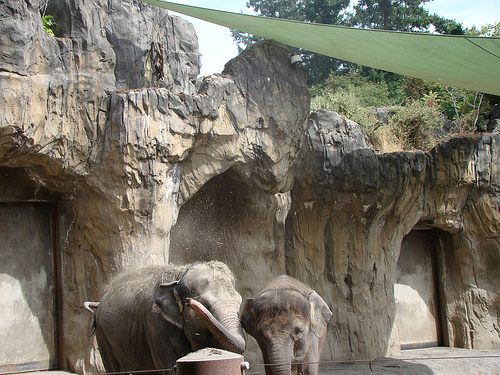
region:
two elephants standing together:
[71, 206, 353, 373]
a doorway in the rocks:
[364, 149, 485, 364]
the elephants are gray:
[70, 249, 345, 371]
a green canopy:
[129, 0, 498, 118]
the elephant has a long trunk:
[69, 251, 274, 373]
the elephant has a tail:
[72, 277, 117, 343]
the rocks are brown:
[19, 14, 484, 271]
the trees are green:
[230, 4, 493, 81]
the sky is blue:
[164, 0, 499, 67]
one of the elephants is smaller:
[78, 246, 346, 373]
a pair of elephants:
[83, 258, 331, 373]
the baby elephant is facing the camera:
[240, 274, 332, 374]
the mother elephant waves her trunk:
[83, 259, 245, 374]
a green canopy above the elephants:
[139, 0, 499, 97]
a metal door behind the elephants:
[0, 202, 60, 374]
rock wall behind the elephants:
[0, 0, 499, 374]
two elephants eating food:
[81, 260, 331, 373]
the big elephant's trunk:
[187, 295, 246, 352]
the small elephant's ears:
[238, 290, 333, 341]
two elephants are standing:
[82, 257, 332, 373]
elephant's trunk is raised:
[183, 295, 246, 355]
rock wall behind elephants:
[0, 0, 498, 374]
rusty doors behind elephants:
[0, 202, 445, 374]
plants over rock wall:
[308, 65, 498, 155]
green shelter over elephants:
[135, 0, 498, 95]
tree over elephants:
[229, 0, 499, 86]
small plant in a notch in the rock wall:
[42, 14, 57, 36]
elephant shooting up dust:
[98, 178, 246, 284]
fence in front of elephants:
[73, 353, 498, 373]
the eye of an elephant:
[289, 320, 304, 337]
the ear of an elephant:
[302, 289, 332, 338]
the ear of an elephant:
[138, 280, 185, 326]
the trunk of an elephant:
[186, 291, 253, 362]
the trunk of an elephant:
[257, 324, 285, 370]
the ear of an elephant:
[231, 290, 260, 338]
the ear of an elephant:
[80, 295, 102, 337]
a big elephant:
[76, 252, 245, 373]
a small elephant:
[240, 270, 335, 374]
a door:
[1, 198, 63, 372]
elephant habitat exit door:
[387, 216, 470, 352]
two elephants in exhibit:
[76, 253, 336, 373]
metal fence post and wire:
[168, 342, 422, 372]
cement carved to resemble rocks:
[12, 97, 497, 234]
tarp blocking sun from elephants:
[198, 5, 499, 100]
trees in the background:
[229, 2, 476, 64]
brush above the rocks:
[304, 57, 486, 149]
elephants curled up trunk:
[185, 295, 249, 351]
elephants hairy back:
[98, 254, 205, 281]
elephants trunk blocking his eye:
[176, 292, 254, 352]